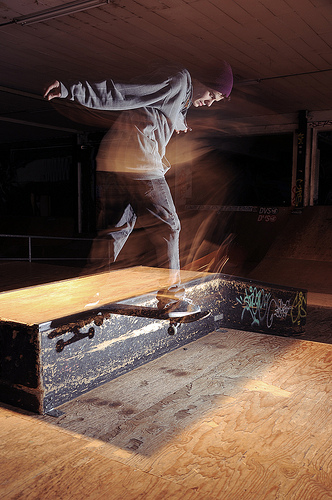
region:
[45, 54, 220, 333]
the boy is doing a skateboard trick on his skateboard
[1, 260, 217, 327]
the top of the ramp is not painted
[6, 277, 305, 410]
the sides of the ramp are painted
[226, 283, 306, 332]
there is graffetti on the side of the ramp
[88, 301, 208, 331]
the boy is standing on a skateboard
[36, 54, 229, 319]
the boy is wearing jeans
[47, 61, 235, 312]
the boy is wearing a sweatshirt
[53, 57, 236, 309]
the boy is wearing a purple beanie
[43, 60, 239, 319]
the image of the boy is blurred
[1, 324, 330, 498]
the second level of the ramp is unpainted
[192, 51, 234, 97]
A violet purple beanie.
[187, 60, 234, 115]
A man focusing intently.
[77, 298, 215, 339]
A skateboard while griniding.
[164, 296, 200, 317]
A see though shoe.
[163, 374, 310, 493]
A light brown wooden deck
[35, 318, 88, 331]
A bar to gind on.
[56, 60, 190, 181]
A grey hoodie sweater.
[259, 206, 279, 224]
Stickers are on the ramp.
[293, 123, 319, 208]
A floor beam for support.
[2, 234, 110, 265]
A metal rail way.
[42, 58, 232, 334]
translucent double exposure of a ghostly skateboarder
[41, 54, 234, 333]
skateboarder wearing a purple knit beanie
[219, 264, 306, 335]
slanted ramp portion has blue white and yellow graffiti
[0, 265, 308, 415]
wooden ramp has heavily chipped blacked painted side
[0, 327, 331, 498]
floor is well worn plywood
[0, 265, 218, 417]
black skateboard is hanging off flat end of ramp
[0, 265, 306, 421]
old looking metal brackets connect ramp to floor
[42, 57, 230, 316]
skateboarder wearing a grey hoodie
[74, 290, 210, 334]
black and white shoes on the skateboard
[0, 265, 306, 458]
skateboard ramp casts a light shadow on the wood floor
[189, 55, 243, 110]
the head of a man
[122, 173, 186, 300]
the leg of a man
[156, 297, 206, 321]
a black and white shoe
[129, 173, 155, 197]
a pocket on the pants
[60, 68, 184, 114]
the arm of a man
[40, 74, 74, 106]
the hand of a man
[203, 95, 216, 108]
the nose of a man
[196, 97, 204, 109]
the mouth of a man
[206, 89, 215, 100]
the eye of a man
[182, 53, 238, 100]
a purple stocking cap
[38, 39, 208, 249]
this is a man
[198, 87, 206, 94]
the man is light skinned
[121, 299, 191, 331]
this is a skate board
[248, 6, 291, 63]
this is the roof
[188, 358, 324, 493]
this is the floor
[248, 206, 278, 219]
this is a writing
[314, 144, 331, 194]
the door is opened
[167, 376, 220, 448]
this is the board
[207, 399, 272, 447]
the board is brown in color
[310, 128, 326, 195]
this is the door